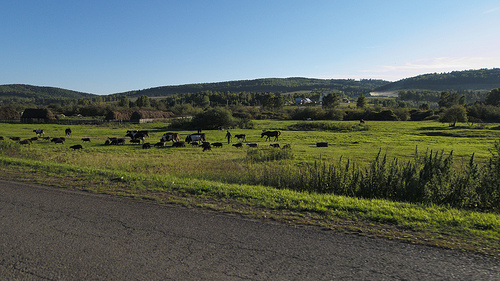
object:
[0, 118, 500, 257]
grass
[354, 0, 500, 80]
clouds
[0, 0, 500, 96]
sky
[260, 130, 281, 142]
horse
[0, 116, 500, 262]
pasture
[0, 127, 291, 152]
livestock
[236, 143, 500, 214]
weeds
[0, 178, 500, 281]
road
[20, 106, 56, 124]
building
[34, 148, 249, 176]
patch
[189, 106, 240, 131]
tree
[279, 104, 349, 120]
bushes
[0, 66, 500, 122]
trees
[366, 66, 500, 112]
hillside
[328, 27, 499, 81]
haze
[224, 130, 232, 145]
man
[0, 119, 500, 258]
field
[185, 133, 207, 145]
cow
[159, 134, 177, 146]
cow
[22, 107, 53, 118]
roof